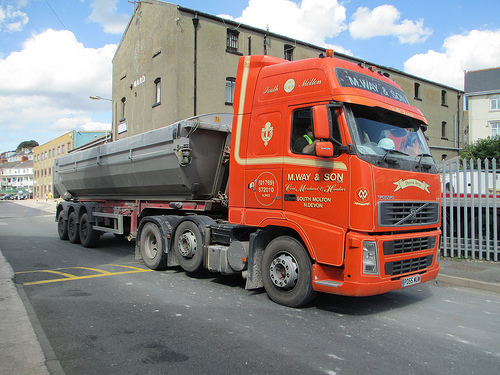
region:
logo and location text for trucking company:
[282, 168, 347, 217]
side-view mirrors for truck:
[303, 98, 346, 168]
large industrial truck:
[39, 46, 450, 311]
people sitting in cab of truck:
[296, 108, 424, 162]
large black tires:
[251, 227, 318, 313]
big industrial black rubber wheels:
[256, 230, 318, 319]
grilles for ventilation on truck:
[376, 188, 446, 290]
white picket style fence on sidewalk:
[437, 154, 499, 255]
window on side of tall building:
[151, 76, 165, 110]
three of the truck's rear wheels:
[50, 203, 107, 247]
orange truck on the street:
[37, 42, 447, 315]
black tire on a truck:
[252, 229, 323, 314]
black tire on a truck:
[167, 210, 212, 279]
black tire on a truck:
[132, 216, 170, 276]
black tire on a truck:
[77, 209, 94, 247]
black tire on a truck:
[66, 207, 80, 242]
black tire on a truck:
[51, 205, 66, 243]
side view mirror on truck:
[306, 98, 344, 170]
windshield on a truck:
[345, 105, 442, 171]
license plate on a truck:
[395, 269, 422, 291]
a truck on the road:
[37, 46, 454, 349]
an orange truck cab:
[46, 19, 456, 374]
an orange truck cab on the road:
[37, 42, 476, 371]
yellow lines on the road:
[9, 204, 260, 374]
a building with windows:
[102, 12, 499, 189]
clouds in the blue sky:
[3, 8, 149, 156]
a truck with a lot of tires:
[50, 111, 447, 336]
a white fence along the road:
[398, 117, 499, 297]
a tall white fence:
[347, 95, 494, 285]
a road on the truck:
[9, 28, 442, 373]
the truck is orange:
[222, 31, 454, 333]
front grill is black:
[369, 191, 453, 295]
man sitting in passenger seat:
[283, 117, 327, 159]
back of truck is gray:
[38, 121, 253, 204]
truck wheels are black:
[50, 196, 372, 323]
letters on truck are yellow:
[278, 156, 351, 204]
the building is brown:
[105, 9, 492, 183]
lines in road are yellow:
[13, 239, 158, 306]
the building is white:
[468, 87, 498, 138]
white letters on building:
[115, 68, 165, 98]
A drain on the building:
[192, 14, 200, 119]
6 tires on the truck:
[52, 204, 307, 303]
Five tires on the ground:
[49, 209, 318, 321]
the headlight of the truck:
[356, 237, 378, 282]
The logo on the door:
[284, 171, 352, 206]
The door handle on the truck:
[282, 187, 298, 209]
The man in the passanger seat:
[287, 99, 332, 204]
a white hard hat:
[373, 134, 400, 151]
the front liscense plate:
[399, 271, 423, 293]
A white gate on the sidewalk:
[460, 148, 495, 265]